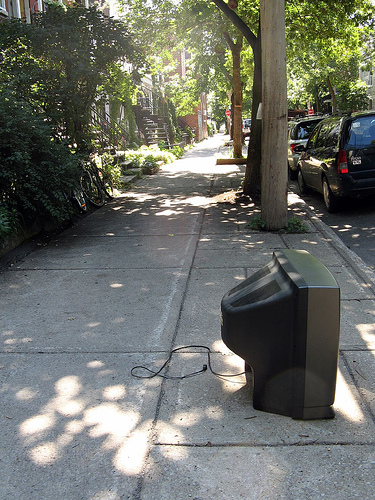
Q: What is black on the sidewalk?
A: A television.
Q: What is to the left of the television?
A: Green trees.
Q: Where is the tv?
A: On the curb.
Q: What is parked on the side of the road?
A: Cars.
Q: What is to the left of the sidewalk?
A: Houses.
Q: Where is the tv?
A: Sidewalk.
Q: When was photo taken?
A: Daytime.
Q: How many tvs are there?
A: One.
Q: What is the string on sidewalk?
A: Cord.